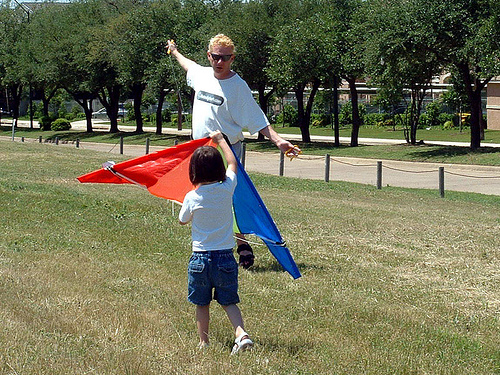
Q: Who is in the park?
A: A man and a young girl.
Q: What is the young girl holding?
A: A kite.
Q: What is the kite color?
A: Blue and red.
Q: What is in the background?
A: Trees.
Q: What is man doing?
A: Flying kite.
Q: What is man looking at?
A: At child.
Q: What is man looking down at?
A: A kite.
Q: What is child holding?
A: A kite.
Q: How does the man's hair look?
A: Short and blonde.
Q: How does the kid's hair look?
A: Short and dark.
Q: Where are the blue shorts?
A: On the child.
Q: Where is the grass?
A: On the ground.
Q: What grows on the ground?
A: Grass.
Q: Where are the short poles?
A: By the road.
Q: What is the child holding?
A: A kite.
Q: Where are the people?
A: In a field.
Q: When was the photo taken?
A: Daytime.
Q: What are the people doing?
A: Trying to fly a kite.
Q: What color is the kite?
A: Rainbow colors.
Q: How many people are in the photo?
A: Two.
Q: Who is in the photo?
A: A man and a child.